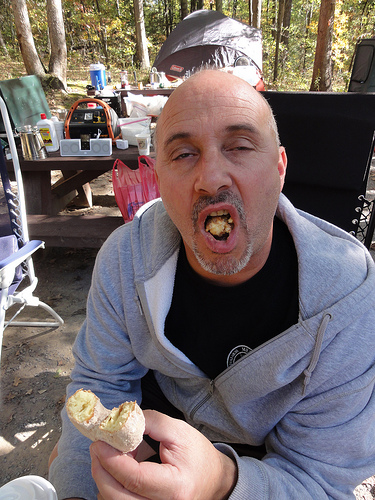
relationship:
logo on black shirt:
[225, 343, 253, 366] [166, 235, 321, 367]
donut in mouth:
[205, 217, 229, 236] [200, 203, 239, 249]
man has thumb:
[48, 68, 374, 500] [142, 406, 188, 445]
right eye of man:
[162, 142, 200, 163] [48, 68, 374, 500]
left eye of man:
[224, 139, 254, 152] [84, 68, 374, 309]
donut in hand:
[67, 376, 157, 460] [88, 409, 227, 499]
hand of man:
[88, 409, 227, 499] [48, 68, 374, 500]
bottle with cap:
[35, 112, 60, 154] [38, 112, 46, 122]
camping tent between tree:
[150, 8, 264, 84] [131, 0, 150, 67]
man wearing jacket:
[48, 68, 374, 500] [48, 193, 372, 497]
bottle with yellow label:
[36, 112, 59, 152] [38, 128, 52, 146]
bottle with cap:
[36, 112, 59, 152] [40, 113, 46, 120]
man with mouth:
[48, 68, 374, 500] [189, 197, 257, 254]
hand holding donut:
[88, 409, 227, 499] [65, 393, 150, 447]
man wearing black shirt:
[48, 68, 374, 500] [164, 208, 300, 379]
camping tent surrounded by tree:
[150, 8, 264, 84] [8, 2, 68, 79]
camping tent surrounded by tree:
[150, 8, 264, 84] [128, 2, 151, 67]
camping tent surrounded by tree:
[150, 8, 264, 84] [271, 3, 292, 88]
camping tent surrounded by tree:
[150, 8, 264, 84] [310, 2, 336, 89]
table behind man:
[3, 118, 166, 218] [55, 58, 373, 438]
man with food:
[48, 68, 374, 500] [203, 216, 235, 238]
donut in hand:
[65, 386, 146, 456] [86, 405, 234, 497]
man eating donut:
[48, 68, 374, 500] [65, 386, 146, 456]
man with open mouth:
[48, 68, 374, 500] [195, 200, 240, 253]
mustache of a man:
[189, 191, 245, 237] [48, 68, 374, 500]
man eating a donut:
[48, 68, 374, 500] [57, 385, 147, 449]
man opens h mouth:
[105, 78, 363, 354] [196, 201, 238, 252]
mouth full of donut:
[196, 201, 238, 252] [205, 217, 232, 236]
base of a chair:
[1, 93, 63, 343] [0, 93, 63, 355]